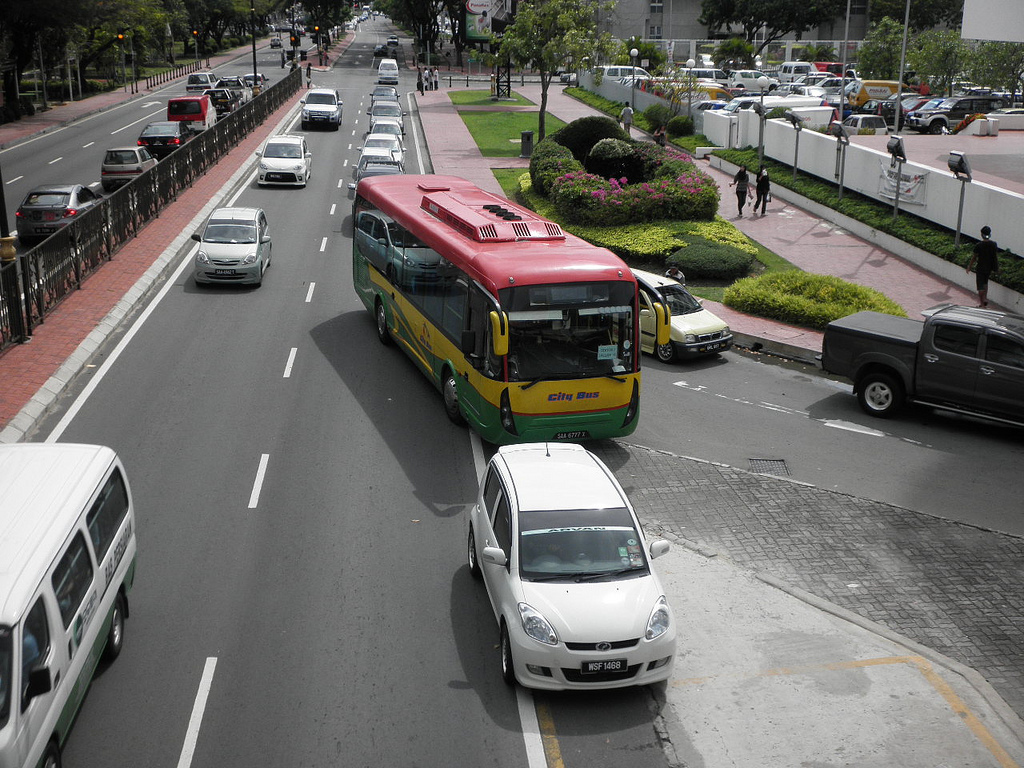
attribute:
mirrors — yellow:
[482, 309, 519, 357]